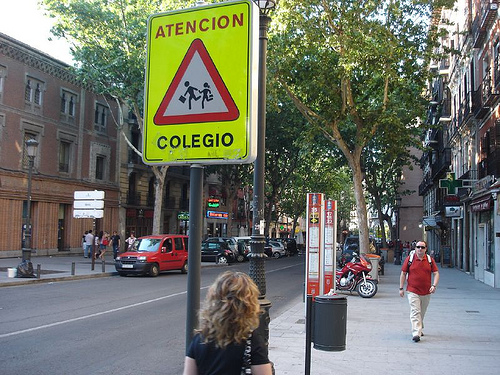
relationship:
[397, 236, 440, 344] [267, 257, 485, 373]
person on sidewalk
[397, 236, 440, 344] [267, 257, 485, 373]
person at sidewalk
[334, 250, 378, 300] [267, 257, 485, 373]
bike on sidewalk